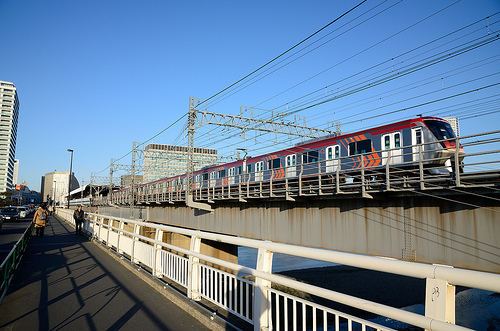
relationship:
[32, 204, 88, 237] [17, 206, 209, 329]
people on sidewalk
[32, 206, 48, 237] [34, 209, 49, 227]
people in jacket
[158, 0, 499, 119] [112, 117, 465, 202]
wire over train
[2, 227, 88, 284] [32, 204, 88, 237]
shadow near people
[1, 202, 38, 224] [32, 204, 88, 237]
cars near people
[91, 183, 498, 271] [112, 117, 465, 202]
bridge under train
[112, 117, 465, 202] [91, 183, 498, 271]
train on bridge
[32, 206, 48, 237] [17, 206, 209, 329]
people on sidewalk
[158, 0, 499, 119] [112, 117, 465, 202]
wire above train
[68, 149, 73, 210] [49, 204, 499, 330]
lamp near rail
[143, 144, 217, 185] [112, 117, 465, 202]
building behind train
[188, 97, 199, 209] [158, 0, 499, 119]
steel near wire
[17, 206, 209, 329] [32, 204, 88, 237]
sidewalk under people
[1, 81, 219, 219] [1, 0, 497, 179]
city under sky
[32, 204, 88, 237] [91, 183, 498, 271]
people near bridge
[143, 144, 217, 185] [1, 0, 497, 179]
building under sky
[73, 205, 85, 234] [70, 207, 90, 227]
person wearing clothing